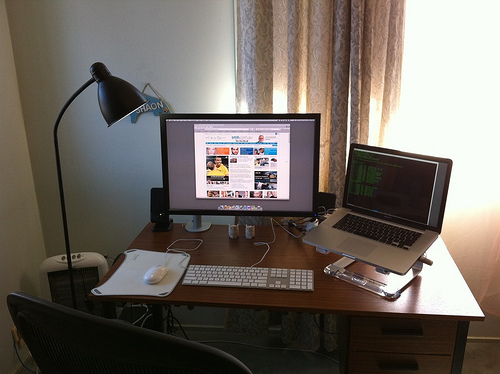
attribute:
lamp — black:
[51, 57, 151, 314]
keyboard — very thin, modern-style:
[183, 261, 318, 290]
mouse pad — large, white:
[92, 247, 192, 296]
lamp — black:
[53, 64, 144, 307]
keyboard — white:
[144, 264, 363, 315]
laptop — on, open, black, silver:
[299, 139, 455, 276]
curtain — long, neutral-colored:
[236, 5, 403, 352]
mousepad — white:
[91, 242, 187, 300]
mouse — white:
[145, 262, 170, 287]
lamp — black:
[53, 61, 148, 268]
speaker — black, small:
[148, 186, 173, 233]